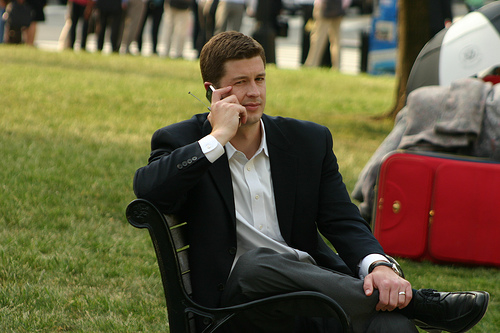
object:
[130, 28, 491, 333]
man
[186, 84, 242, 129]
phone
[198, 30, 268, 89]
hair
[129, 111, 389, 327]
shirt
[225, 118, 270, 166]
collar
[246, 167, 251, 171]
button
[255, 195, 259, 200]
button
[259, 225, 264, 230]
button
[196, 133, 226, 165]
cuff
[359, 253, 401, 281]
cuff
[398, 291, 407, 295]
ring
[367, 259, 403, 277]
watch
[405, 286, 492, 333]
shoe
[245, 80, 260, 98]
nose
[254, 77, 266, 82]
eye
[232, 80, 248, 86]
eye